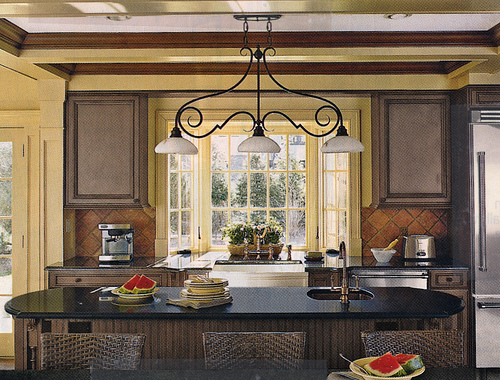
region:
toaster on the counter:
[403, 225, 440, 261]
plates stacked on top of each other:
[178, 273, 230, 302]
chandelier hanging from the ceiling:
[156, 10, 372, 184]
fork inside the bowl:
[334, 348, 374, 375]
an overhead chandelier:
[155, 13, 365, 153]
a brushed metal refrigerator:
[453, 109, 498, 368]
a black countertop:
[2, 286, 462, 321]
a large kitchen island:
[6, 283, 464, 367]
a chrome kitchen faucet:
[337, 240, 351, 305]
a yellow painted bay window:
[168, 120, 349, 260]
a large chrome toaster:
[400, 234, 435, 267]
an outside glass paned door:
[1, 128, 26, 358]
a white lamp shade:
[155, 138, 198, 154]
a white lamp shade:
[237, 136, 281, 151]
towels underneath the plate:
[163, 293, 242, 312]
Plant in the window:
[222, 215, 291, 258]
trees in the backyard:
[210, 146, 310, 215]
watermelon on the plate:
[116, 265, 156, 300]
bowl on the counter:
[341, 352, 408, 378]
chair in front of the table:
[197, 323, 317, 368]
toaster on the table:
[396, 223, 444, 263]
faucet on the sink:
[330, 233, 374, 309]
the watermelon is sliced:
[366, 356, 424, 373]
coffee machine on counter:
[95, 222, 150, 267]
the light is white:
[165, 126, 368, 163]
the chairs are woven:
[41, 332, 476, 361]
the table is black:
[43, 365, 486, 379]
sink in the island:
[312, 281, 377, 301]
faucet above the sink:
[325, 242, 368, 315]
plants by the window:
[207, 184, 312, 259]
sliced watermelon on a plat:
[113, 270, 158, 300]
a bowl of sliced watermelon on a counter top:
[344, 349, 436, 379]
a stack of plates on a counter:
[182, 275, 235, 307]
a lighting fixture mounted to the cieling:
[137, 11, 367, 161]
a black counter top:
[5, 280, 467, 322]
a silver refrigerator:
[457, 106, 499, 374]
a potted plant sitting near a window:
[220, 217, 288, 257]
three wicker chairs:
[30, 329, 480, 375]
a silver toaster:
[400, 228, 441, 265]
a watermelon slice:
[365, 355, 405, 378]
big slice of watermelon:
[132, 273, 155, 292]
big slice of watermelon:
[119, 274, 139, 292]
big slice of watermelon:
[364, 351, 406, 376]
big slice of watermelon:
[394, 352, 425, 374]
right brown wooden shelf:
[65, 88, 153, 203]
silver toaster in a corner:
[401, 231, 441, 266]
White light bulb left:
[160, 127, 198, 157]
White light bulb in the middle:
[234, 135, 286, 156]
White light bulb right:
[326, 137, 362, 154]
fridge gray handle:
[478, 148, 486, 269]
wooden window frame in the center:
[203, 163, 255, 214]